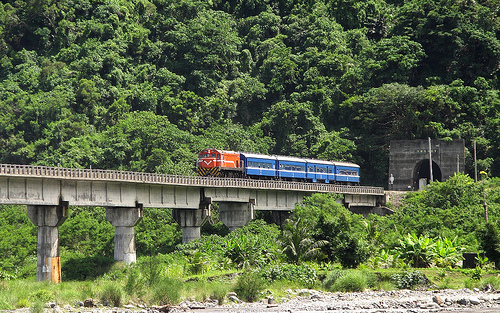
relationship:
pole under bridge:
[24, 203, 74, 288] [0, 159, 388, 288]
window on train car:
[246, 160, 253, 169] [240, 149, 278, 180]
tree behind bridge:
[164, 7, 246, 93] [0, 159, 388, 288]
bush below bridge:
[391, 233, 441, 270] [0, 159, 388, 288]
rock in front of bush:
[430, 291, 448, 307] [391, 233, 441, 270]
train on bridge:
[192, 145, 367, 190] [0, 159, 388, 288]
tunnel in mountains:
[387, 134, 465, 191] [3, 1, 500, 203]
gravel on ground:
[6, 286, 500, 312] [2, 233, 500, 311]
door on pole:
[42, 255, 63, 284] [24, 203, 74, 288]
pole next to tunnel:
[425, 136, 435, 184] [387, 134, 465, 191]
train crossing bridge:
[192, 145, 367, 190] [0, 159, 388, 288]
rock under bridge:
[430, 291, 448, 307] [0, 159, 388, 288]